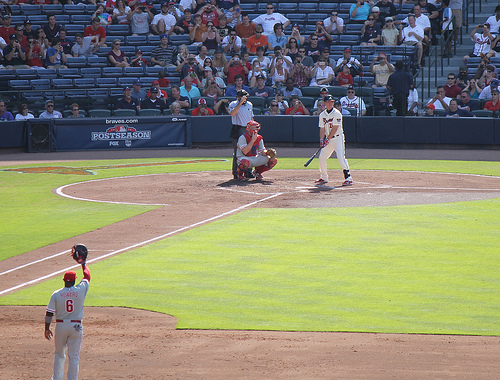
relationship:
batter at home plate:
[313, 93, 381, 196] [298, 181, 332, 192]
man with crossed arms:
[158, 74, 193, 116] [167, 96, 194, 109]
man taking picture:
[369, 49, 395, 84] [18, 95, 481, 374]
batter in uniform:
[314, 94, 354, 186] [315, 110, 355, 181]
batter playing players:
[314, 94, 354, 186] [228, 87, 253, 178]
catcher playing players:
[236, 120, 279, 181] [228, 87, 253, 178]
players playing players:
[48, 260, 90, 378] [228, 87, 253, 178]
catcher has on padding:
[237, 120, 280, 185] [236, 132, 277, 179]